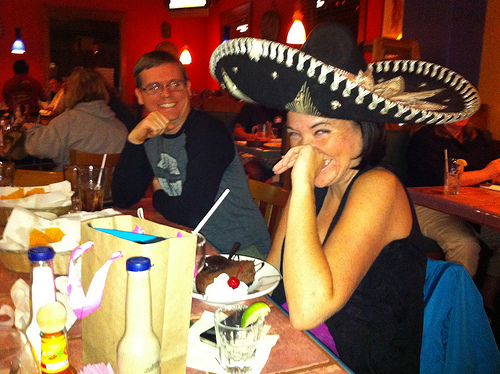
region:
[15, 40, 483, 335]
A crowded restaurant.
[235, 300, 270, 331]
A lime wedge on the rim of the glass.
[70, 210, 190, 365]
A gift bag.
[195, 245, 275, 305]
A piece of cake.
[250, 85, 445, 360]
The woman is laughing.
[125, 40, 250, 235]
The man is smiling.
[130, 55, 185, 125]
The man is wearing glasses.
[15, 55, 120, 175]
The person is wearing a gray hoodie.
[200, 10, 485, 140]
The woman is wearing a sombrero.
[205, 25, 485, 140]
The sombrero is black and gold.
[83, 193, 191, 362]
brown paper bag with gifts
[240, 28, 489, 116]
large black and silver sombrero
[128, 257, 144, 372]
beer bottle pepper shaker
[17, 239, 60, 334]
beer bottle salt shaker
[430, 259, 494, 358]
blue windbreaker on seat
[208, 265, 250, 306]
whip cream with a cherry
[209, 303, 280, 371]
drink with a lime on the cup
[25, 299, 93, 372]
bottle of hot sauce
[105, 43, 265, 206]
man smiling at the woman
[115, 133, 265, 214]
black and grey long sleeve shirt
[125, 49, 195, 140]
A man looks on smiling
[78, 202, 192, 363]
A yellow paper gift bag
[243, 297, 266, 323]
A slice of fresh green lime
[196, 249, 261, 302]
A piece of chocolate cake with whip cream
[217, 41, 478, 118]
A black big rim Mexican hat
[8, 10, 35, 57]
A hanging lamp in a blue shade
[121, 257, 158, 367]
A bottle of Mexican beer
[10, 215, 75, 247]
Some tortilla chips in a basket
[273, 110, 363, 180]
A woman is smiling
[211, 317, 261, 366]
A shot of Mexican liquor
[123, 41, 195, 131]
a man wearing glasses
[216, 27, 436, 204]
a woman wearing a large hat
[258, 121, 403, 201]
a woman covering her face with her hand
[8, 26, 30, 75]
a blue light hanging on a wall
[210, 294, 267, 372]
a glass with a lime on it.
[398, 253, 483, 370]
a blue jacket hanging on a chair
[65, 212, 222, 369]
a brown paper bag on a table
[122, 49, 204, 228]
a man wearing a black and grey shirt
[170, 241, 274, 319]
a plate of food on a table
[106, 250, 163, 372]
a bottle with a blue lid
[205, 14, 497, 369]
woman wearing large black sombrero hat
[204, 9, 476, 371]
woman laughing wearing black sleeveless dress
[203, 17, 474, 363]
woman holding hand to face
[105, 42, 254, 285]
man resting head in hand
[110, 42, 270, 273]
man sitting at table with woman smiling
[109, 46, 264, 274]
man wearing long sleeved tee shirt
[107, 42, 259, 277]
blond man wearing glasses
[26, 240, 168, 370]
two bottles with blue caps on table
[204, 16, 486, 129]
black sombrero hat with silver trim and embroidery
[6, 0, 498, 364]
indoor Mexican restaurant scene